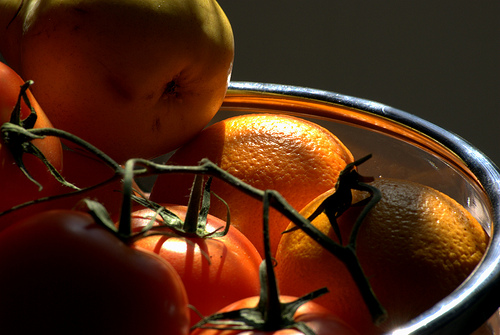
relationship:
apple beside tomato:
[21, 0, 235, 159] [1, 63, 65, 229]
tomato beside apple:
[1, 63, 65, 229] [21, 0, 235, 159]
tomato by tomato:
[1, 208, 189, 334] [111, 204, 264, 328]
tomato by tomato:
[1, 208, 189, 334] [187, 293, 361, 334]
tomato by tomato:
[1, 208, 189, 334] [1, 63, 65, 229]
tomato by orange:
[111, 204, 264, 328] [149, 114, 358, 260]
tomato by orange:
[187, 293, 361, 334] [273, 178, 489, 334]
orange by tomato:
[149, 114, 358, 260] [111, 204, 264, 328]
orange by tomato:
[273, 178, 489, 334] [187, 293, 361, 334]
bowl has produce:
[125, 81, 498, 335] [1, 1, 490, 334]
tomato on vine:
[1, 208, 189, 334] [25, 129, 387, 329]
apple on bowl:
[21, 0, 235, 159] [125, 81, 498, 335]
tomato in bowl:
[1, 63, 65, 229] [125, 81, 498, 335]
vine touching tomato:
[25, 129, 387, 329] [1, 63, 65, 229]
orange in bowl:
[149, 114, 358, 260] [125, 81, 498, 335]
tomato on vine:
[111, 204, 264, 328] [25, 129, 387, 329]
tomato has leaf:
[111, 204, 264, 328] [132, 176, 233, 237]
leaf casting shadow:
[132, 176, 233, 237] [154, 239, 229, 280]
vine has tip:
[25, 129, 387, 329] [373, 312, 387, 328]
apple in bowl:
[21, 0, 235, 159] [125, 81, 498, 335]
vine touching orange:
[25, 129, 387, 329] [273, 178, 489, 334]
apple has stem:
[21, 0, 235, 159] [165, 81, 182, 96]